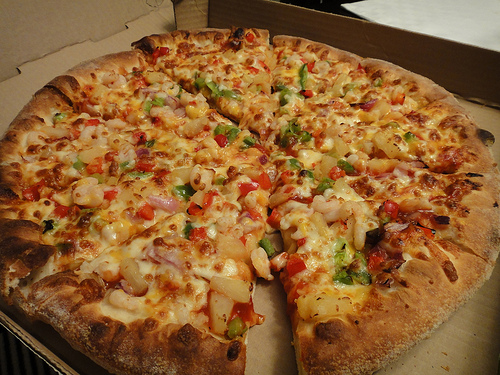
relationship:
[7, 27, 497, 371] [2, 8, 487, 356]
pizza in box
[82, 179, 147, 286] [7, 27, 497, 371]
onion on pizza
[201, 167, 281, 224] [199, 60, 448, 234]
tomato on pizza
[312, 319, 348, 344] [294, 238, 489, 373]
bubble on crust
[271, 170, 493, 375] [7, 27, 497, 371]
pizza triangle on pizza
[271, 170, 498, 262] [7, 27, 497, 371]
pizza triangle on pizza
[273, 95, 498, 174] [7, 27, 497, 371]
pizza triangle on pizza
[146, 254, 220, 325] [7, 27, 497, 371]
cheese on pizza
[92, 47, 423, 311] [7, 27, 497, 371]
seasoning on pizza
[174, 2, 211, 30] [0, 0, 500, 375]
corner on box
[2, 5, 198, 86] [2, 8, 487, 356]
fold on box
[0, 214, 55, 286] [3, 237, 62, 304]
crust on pizza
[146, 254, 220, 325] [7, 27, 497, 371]
cheese are on pizza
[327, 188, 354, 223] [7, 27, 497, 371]
cheese on pizza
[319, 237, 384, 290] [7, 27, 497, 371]
pepper on pizza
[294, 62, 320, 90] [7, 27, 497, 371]
pepper on pizza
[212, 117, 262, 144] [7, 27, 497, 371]
pepper on pizza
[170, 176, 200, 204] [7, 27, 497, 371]
pepper on pizza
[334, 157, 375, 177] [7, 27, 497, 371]
pepper on pizza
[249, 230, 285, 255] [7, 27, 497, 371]
pepper on pizza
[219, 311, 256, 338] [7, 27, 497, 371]
pepper on pizza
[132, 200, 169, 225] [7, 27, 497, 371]
tomato on pizza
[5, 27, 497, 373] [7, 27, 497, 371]
onion on pizza